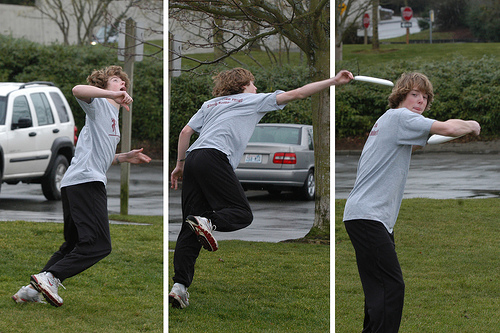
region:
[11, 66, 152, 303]
Boy running on the grass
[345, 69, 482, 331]
Boy throwing white frisbee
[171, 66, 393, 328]
Frisbee caught by young boy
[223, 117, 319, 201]
Back of light colored car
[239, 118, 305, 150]
Back window of light colored car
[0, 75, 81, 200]
Driver's side of white suv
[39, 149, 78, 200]
Left rear tire of white suv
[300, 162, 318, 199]
Right rear tire of light colored car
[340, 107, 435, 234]
Gray tee shirt worn by young boy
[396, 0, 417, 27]
Red and white stop sign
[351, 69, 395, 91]
a white Frisbee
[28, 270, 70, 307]
a boy's tennis shoe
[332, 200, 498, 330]
a section of green grass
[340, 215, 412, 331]
a boy's black pants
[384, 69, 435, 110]
a boy's brown hair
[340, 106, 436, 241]
a man's gray shirt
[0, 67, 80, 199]
part of a small white jeep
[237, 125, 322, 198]
the back of a gray car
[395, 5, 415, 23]
a red and white stop sign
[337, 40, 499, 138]
a large green bush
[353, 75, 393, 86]
the white frisbee being thrown into the air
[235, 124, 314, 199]
the gray parked car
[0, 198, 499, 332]
the green grass on the ground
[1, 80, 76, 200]
the parked white SUV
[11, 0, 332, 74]
the bare branches on the trees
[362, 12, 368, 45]
the red STOP sign in the distance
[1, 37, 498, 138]
the green bushes lining the parking lot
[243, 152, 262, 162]
the license plate on the back of the gray car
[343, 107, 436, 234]
the short sleeved gray shirt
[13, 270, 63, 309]
the white tennis shoes on the boy's feet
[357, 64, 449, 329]
boy throwing white frisbee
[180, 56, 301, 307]
boy throwing white frisbee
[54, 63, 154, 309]
boy throwing white frisbee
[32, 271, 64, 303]
nike shoes on boy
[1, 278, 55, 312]
nike shoes on boy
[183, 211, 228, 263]
nike shoes on boy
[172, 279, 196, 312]
nike shoes on boy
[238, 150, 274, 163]
license plate on car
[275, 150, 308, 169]
tail light of car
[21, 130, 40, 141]
door handle on car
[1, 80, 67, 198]
white suv with black trim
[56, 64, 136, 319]
boy wearing gray t shirt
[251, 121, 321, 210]
tan car with red tail light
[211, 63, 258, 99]
medium length brown hair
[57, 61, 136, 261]
boy chasing after object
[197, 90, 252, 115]
red writing on gray t shirt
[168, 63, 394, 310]
boy catching frisbee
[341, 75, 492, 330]
boy throwing frisbee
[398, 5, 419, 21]
red stop sign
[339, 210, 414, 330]
black sweat pants